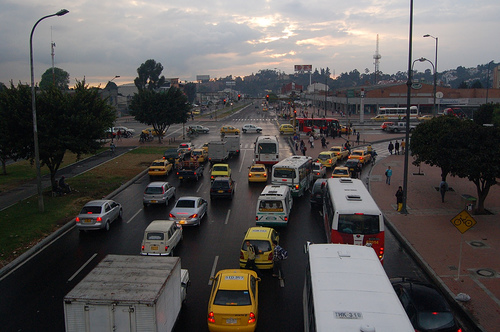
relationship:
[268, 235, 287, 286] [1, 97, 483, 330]
person on street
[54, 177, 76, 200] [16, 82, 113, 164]
person under tree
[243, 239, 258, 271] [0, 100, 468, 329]
men on road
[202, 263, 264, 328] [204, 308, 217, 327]
taxi cab with brake light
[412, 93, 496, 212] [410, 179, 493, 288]
trees on sidewalk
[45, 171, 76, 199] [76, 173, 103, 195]
people sitting on grass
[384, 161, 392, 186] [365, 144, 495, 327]
person walking down sidewalk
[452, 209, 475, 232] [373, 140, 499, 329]
sign on sidewalk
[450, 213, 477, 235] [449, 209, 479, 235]
bike on sign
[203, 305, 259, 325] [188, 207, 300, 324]
lights on cab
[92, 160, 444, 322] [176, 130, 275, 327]
cars on street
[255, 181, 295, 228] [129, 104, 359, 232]
vehicle in intersection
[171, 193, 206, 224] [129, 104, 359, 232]
vehicle in intersection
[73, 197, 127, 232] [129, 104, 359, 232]
vehicle in intersection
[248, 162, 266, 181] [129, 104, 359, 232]
vehicle in intersection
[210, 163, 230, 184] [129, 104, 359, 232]
vehicle in intersection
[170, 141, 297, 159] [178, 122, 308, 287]
crosswalk across road